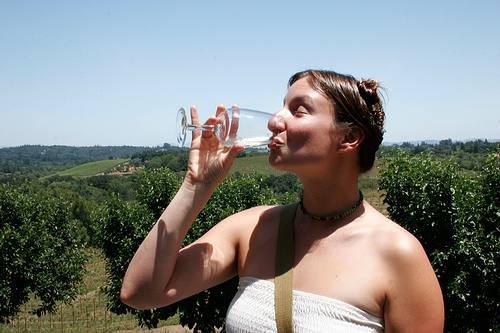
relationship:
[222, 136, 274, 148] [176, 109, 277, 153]
liquid in glass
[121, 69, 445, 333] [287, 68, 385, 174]
woman has hair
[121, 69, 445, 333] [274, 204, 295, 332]
woman wearing strap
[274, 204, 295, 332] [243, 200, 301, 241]
strap across shoulder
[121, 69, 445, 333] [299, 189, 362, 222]
woman wearing necklace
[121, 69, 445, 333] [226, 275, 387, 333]
woman wearing shirt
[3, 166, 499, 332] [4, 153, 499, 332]
tree with leaves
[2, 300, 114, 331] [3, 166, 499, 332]
fence near trees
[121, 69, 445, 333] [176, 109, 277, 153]
woman holding glass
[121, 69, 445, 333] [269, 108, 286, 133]
woman has nose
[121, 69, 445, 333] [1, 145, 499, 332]
woman in vineyard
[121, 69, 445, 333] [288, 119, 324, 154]
woman has cheeks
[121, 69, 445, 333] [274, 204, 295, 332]
woman has bag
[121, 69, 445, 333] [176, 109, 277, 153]
woman has glass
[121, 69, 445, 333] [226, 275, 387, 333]
woman wears shirt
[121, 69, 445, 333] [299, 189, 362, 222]
woman has necklace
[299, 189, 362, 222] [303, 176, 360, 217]
necklace on neck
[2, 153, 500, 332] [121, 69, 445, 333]
bushes behind woman